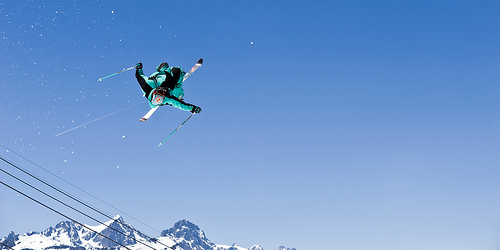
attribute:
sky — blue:
[2, 3, 494, 248]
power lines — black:
[2, 157, 162, 249]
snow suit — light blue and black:
[148, 69, 187, 101]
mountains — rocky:
[151, 200, 228, 240]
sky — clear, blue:
[322, 101, 419, 205]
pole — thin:
[154, 107, 202, 148]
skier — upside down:
[101, 56, 204, 148]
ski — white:
[140, 57, 205, 125]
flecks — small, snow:
[96, 68, 106, 87]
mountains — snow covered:
[0, 202, 274, 249]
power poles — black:
[41, 107, 176, 151]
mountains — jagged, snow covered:
[3, 213, 293, 248]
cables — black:
[0, 142, 179, 247]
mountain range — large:
[4, 216, 262, 248]